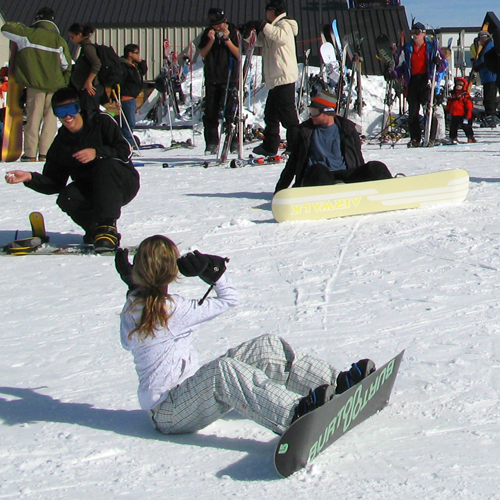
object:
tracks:
[314, 223, 352, 337]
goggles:
[52, 102, 83, 118]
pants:
[52, 158, 144, 230]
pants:
[146, 329, 346, 439]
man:
[4, 79, 145, 256]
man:
[273, 93, 396, 199]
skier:
[104, 233, 408, 475]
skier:
[3, 7, 80, 163]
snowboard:
[270, 166, 468, 224]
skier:
[248, 4, 308, 164]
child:
[443, 77, 478, 144]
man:
[391, 22, 449, 153]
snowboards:
[315, 38, 339, 83]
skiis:
[347, 50, 365, 122]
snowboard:
[274, 352, 406, 479]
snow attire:
[24, 112, 130, 193]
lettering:
[305, 438, 320, 465]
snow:
[405, 264, 497, 497]